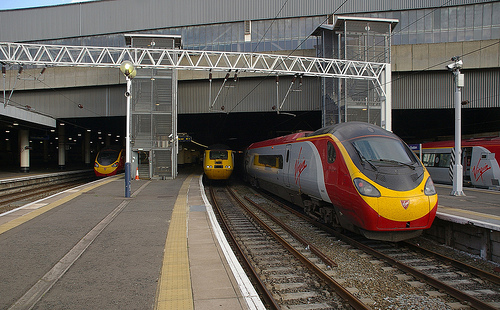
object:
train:
[200, 144, 236, 184]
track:
[210, 181, 362, 308]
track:
[0, 175, 53, 214]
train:
[94, 149, 126, 177]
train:
[243, 121, 438, 243]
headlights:
[353, 177, 381, 198]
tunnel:
[0, 106, 498, 180]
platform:
[0, 174, 266, 310]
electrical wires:
[220, 0, 500, 131]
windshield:
[209, 151, 228, 160]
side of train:
[0, 0, 500, 310]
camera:
[446, 55, 464, 71]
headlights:
[112, 162, 119, 167]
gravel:
[355, 267, 426, 298]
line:
[198, 172, 268, 310]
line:
[150, 174, 194, 310]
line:
[241, 193, 337, 269]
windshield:
[351, 136, 423, 166]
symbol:
[401, 199, 410, 210]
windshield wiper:
[350, 142, 416, 171]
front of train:
[325, 121, 438, 242]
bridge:
[0, 0, 500, 92]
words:
[294, 146, 307, 188]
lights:
[120, 60, 136, 197]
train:
[408, 135, 499, 188]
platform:
[419, 184, 500, 232]